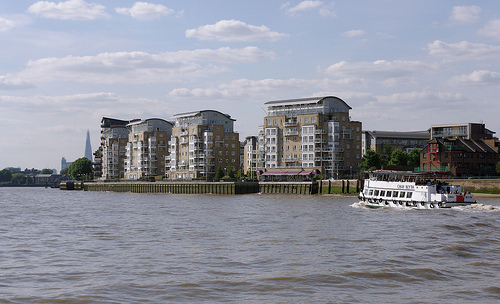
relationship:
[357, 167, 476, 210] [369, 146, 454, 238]
boat on river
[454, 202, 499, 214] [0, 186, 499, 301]
waves on river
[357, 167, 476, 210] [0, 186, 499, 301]
boat on river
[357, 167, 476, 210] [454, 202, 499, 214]
boat on waves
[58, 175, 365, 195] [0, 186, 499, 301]
boat dock on river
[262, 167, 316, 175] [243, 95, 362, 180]
awning on building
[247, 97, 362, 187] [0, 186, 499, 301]
apartment by river